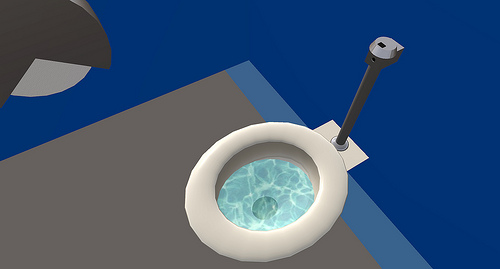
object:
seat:
[185, 122, 347, 263]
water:
[217, 157, 315, 231]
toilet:
[184, 118, 370, 262]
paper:
[10, 59, 92, 99]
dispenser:
[0, 0, 112, 109]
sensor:
[369, 56, 378, 63]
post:
[338, 36, 405, 146]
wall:
[251, 1, 500, 268]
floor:
[0, 70, 385, 268]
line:
[225, 60, 432, 268]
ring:
[328, 136, 350, 153]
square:
[315, 119, 369, 171]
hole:
[252, 196, 278, 220]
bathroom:
[1, 0, 500, 268]